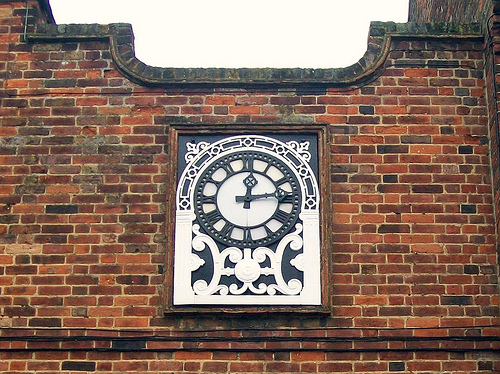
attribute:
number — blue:
[241, 156, 247, 166]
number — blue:
[263, 161, 272, 173]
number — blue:
[273, 175, 288, 185]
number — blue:
[273, 208, 288, 223]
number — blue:
[240, 228, 252, 240]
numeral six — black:
[243, 227, 255, 242]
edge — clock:
[227, 204, 252, 257]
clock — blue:
[164, 124, 326, 312]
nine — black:
[200, 192, 217, 204]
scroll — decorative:
[191, 223, 304, 294]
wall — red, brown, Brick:
[305, 58, 472, 323]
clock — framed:
[158, 109, 344, 321]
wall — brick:
[3, 4, 498, 371]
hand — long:
[253, 187, 291, 202]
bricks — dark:
[328, 84, 479, 93]